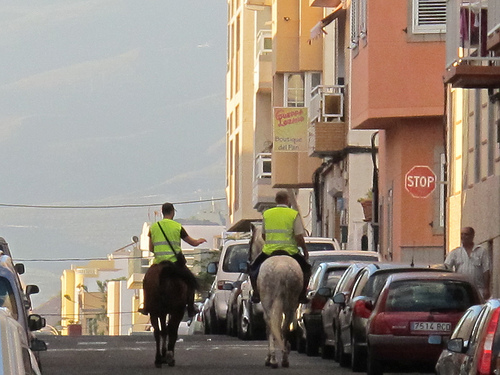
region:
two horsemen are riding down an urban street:
[94, 175, 374, 372]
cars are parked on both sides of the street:
[2, 232, 499, 367]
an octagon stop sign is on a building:
[398, 157, 465, 216]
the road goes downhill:
[9, 285, 338, 374]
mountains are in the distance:
[3, 213, 225, 332]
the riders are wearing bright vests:
[148, 207, 300, 264]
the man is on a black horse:
[135, 202, 209, 368]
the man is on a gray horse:
[246, 191, 313, 373]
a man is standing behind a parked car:
[427, 213, 499, 351]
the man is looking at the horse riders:
[143, 184, 490, 356]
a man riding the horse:
[119, 156, 196, 340]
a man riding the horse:
[225, 161, 326, 371]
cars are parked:
[315, 208, 403, 364]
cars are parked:
[198, 186, 356, 360]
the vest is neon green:
[128, 190, 210, 262]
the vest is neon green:
[251, 190, 316, 269]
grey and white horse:
[246, 253, 304, 365]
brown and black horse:
[145, 263, 197, 368]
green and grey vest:
[262, 207, 297, 252]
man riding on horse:
[143, 203, 203, 366]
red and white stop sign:
[404, 163, 437, 198]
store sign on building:
[273, 105, 308, 152]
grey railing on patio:
[447, 3, 499, 72]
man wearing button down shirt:
[438, 228, 490, 300]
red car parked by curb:
[366, 272, 478, 368]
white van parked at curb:
[215, 235, 339, 327]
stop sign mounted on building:
[400, 159, 442, 205]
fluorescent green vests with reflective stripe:
[142, 204, 312, 264]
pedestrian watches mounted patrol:
[432, 210, 499, 299]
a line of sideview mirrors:
[5, 231, 47, 374]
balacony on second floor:
[285, 77, 355, 131]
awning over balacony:
[298, 1, 355, 53]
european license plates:
[405, 313, 456, 345]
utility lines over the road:
[3, 171, 230, 294]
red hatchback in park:
[363, 265, 488, 360]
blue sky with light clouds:
[5, 3, 230, 234]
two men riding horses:
[124, 170, 316, 370]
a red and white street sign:
[391, 144, 453, 223]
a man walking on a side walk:
[446, 207, 483, 330]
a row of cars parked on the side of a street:
[287, 208, 497, 372]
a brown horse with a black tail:
[140, 244, 194, 349]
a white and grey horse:
[246, 245, 310, 362]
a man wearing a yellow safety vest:
[256, 185, 312, 270]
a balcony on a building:
[253, 18, 277, 77]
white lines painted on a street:
[33, 333, 268, 365]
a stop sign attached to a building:
[393, 143, 464, 209]